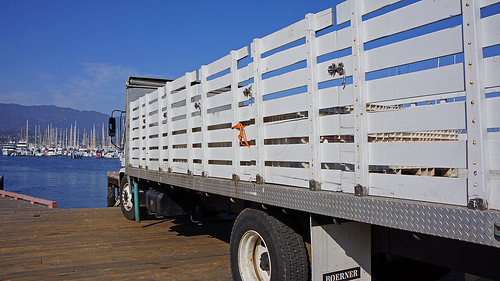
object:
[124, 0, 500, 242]
flat bed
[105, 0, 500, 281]
truck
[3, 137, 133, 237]
dock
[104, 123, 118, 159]
boats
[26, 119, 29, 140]
masts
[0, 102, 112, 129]
mountain range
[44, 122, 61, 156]
boat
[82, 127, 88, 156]
boat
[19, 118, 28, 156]
boat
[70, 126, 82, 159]
boat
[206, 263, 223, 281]
ground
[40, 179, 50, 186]
water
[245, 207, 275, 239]
edge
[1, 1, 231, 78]
sky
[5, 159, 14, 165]
water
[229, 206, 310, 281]
back wheel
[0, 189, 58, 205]
red rail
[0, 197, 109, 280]
floor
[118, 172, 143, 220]
tire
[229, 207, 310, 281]
tire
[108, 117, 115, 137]
mirror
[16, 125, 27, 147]
yachts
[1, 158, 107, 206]
ocean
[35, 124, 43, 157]
docked boat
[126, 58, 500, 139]
planks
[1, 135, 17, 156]
boats